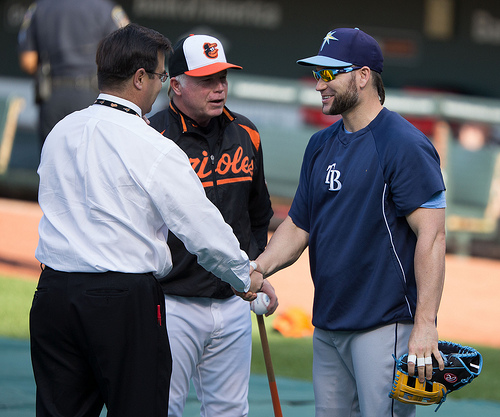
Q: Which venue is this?
A: This is a field.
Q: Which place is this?
A: It is a field.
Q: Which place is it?
A: It is a field.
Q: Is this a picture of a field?
A: Yes, it is showing a field.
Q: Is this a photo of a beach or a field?
A: It is showing a field.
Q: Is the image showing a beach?
A: No, the picture is showing a field.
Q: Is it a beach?
A: No, it is a field.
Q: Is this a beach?
A: No, it is a field.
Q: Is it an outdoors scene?
A: Yes, it is outdoors.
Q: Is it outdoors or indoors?
A: It is outdoors.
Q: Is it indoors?
A: No, it is outdoors.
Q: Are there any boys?
A: No, there are no boys.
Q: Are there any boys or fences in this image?
A: No, there are no boys or fences.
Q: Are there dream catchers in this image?
A: No, there are no dream catchers.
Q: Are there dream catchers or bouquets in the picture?
A: No, there are no dream catchers or bouquets.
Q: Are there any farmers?
A: No, there are no farmers.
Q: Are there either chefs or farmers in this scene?
A: No, there are no farmers or chefs.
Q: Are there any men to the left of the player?
A: Yes, there is a man to the left of the player.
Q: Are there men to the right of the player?
A: No, the man is to the left of the player.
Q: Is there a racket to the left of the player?
A: No, there is a man to the left of the player.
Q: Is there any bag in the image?
A: No, there are no bags.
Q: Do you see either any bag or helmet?
A: No, there are no bags or helmets.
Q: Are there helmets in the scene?
A: No, there are no helmets.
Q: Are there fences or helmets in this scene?
A: No, there are no helmets or fences.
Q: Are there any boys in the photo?
A: No, there are no boys.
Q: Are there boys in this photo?
A: No, there are no boys.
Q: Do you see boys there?
A: No, there are no boys.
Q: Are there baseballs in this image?
A: Yes, there is a baseball.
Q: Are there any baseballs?
A: Yes, there is a baseball.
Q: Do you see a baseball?
A: Yes, there is a baseball.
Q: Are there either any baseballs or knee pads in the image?
A: Yes, there is a baseball.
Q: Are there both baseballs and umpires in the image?
A: No, there is a baseball but no umpires.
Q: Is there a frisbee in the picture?
A: No, there are no frisbees.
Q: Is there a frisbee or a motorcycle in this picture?
A: No, there are no frisbees or motorcycles.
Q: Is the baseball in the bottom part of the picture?
A: Yes, the baseball is in the bottom of the image.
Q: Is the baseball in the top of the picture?
A: No, the baseball is in the bottom of the image.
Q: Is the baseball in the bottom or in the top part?
A: The baseball is in the bottom of the image.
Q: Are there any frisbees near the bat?
A: No, there is a baseball near the bat.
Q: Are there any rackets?
A: No, there are no rackets.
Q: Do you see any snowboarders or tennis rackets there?
A: No, there are no tennis rackets or snowboarders.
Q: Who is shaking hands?
A: The player is shaking hands.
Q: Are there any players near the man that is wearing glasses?
A: Yes, there is a player near the man.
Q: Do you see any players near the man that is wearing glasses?
A: Yes, there is a player near the man.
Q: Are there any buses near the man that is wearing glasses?
A: No, there is a player near the man.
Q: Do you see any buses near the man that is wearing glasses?
A: No, there is a player near the man.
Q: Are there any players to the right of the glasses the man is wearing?
A: Yes, there is a player to the right of the glasses.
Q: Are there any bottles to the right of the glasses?
A: No, there is a player to the right of the glasses.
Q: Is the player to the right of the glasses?
A: Yes, the player is to the right of the glasses.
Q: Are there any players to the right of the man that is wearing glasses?
A: Yes, there is a player to the right of the man.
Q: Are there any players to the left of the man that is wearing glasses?
A: No, the player is to the right of the man.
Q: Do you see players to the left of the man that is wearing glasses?
A: No, the player is to the right of the man.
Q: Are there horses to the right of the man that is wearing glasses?
A: No, there is a player to the right of the man.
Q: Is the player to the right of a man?
A: Yes, the player is to the right of a man.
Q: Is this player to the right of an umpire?
A: No, the player is to the right of a man.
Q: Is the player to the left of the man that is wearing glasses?
A: No, the player is to the right of the man.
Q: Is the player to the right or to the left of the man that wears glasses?
A: The player is to the right of the man.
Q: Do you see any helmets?
A: No, there are no helmets.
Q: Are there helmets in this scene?
A: No, there are no helmets.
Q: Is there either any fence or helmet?
A: No, there are no helmets or fences.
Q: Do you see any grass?
A: Yes, there is grass.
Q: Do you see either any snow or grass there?
A: Yes, there is grass.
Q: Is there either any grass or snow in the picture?
A: Yes, there is grass.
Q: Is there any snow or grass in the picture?
A: Yes, there is grass.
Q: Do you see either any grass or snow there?
A: Yes, there is grass.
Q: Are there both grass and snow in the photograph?
A: No, there is grass but no snow.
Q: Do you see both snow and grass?
A: No, there is grass but no snow.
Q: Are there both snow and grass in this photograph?
A: No, there is grass but no snow.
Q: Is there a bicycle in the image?
A: No, there are no bicycles.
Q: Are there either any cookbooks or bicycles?
A: No, there are no bicycles or cookbooks.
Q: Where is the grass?
A: The grass is on the field.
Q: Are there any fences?
A: No, there are no fences.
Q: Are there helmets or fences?
A: No, there are no fences or helmets.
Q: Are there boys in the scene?
A: No, there are no boys.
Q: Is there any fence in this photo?
A: No, there are no fences.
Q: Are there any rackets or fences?
A: No, there are no fences or rackets.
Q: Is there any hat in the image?
A: Yes, there is a hat.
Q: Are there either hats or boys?
A: Yes, there is a hat.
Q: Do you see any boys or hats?
A: Yes, there is a hat.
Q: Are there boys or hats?
A: Yes, there is a hat.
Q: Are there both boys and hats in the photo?
A: No, there is a hat but no boys.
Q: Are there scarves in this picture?
A: No, there are no scarves.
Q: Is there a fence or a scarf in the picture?
A: No, there are no scarves or fences.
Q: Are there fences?
A: No, there are no fences.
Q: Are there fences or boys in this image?
A: No, there are no fences or boys.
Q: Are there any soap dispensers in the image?
A: No, there are no soap dispensers.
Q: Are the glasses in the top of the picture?
A: Yes, the glasses are in the top of the image.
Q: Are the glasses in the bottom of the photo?
A: No, the glasses are in the top of the image.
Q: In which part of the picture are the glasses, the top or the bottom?
A: The glasses are in the top of the image.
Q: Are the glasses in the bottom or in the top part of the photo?
A: The glasses are in the top of the image.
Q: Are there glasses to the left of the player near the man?
A: Yes, there are glasses to the left of the player.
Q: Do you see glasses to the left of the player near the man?
A: Yes, there are glasses to the left of the player.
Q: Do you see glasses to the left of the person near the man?
A: Yes, there are glasses to the left of the player.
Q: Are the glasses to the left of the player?
A: Yes, the glasses are to the left of the player.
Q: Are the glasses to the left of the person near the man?
A: Yes, the glasses are to the left of the player.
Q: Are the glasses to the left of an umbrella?
A: No, the glasses are to the left of the player.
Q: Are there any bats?
A: Yes, there is a bat.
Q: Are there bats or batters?
A: Yes, there is a bat.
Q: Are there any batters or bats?
A: Yes, there is a bat.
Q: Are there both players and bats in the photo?
A: Yes, there are both a bat and a player.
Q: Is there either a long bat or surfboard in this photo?
A: Yes, there is a long bat.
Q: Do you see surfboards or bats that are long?
A: Yes, the bat is long.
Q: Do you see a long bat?
A: Yes, there is a long bat.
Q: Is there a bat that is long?
A: Yes, there is a bat that is long.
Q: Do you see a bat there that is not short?
A: Yes, there is a long bat.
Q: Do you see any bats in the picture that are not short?
A: Yes, there is a long bat.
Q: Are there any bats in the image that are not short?
A: Yes, there is a long bat.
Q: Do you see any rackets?
A: No, there are no rackets.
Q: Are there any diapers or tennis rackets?
A: No, there are no tennis rackets or diapers.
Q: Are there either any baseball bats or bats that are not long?
A: No, there is a bat but it is long.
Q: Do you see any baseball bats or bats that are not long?
A: No, there is a bat but it is long.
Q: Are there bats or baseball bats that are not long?
A: No, there is a bat but it is long.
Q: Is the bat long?
A: Yes, the bat is long.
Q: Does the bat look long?
A: Yes, the bat is long.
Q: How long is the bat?
A: The bat is long.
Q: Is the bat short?
A: No, the bat is long.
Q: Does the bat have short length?
A: No, the bat is long.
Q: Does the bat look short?
A: No, the bat is long.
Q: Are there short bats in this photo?
A: No, there is a bat but it is long.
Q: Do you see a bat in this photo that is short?
A: No, there is a bat but it is long.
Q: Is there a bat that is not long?
A: No, there is a bat but it is long.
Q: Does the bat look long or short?
A: The bat is long.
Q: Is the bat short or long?
A: The bat is long.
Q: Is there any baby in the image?
A: No, there are no babies.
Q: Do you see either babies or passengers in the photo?
A: No, there are no babies or passengers.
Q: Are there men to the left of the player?
A: Yes, there is a man to the left of the player.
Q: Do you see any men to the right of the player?
A: No, the man is to the left of the player.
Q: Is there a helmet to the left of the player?
A: No, there is a man to the left of the player.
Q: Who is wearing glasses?
A: The man is wearing glasses.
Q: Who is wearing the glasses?
A: The man is wearing glasses.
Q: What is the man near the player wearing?
A: The man is wearing glasses.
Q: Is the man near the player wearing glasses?
A: Yes, the man is wearing glasses.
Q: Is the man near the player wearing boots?
A: No, the man is wearing glasses.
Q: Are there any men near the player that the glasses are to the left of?
A: Yes, there is a man near the player.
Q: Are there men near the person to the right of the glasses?
A: Yes, there is a man near the player.